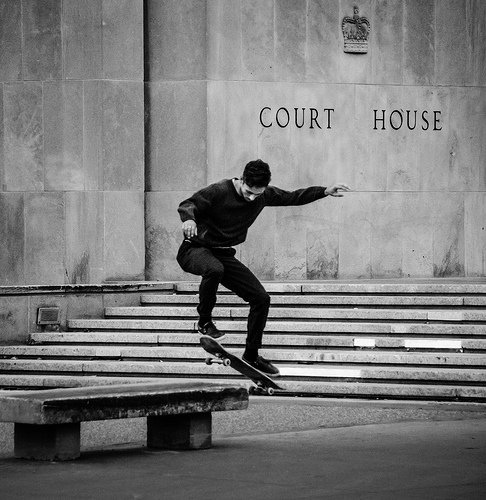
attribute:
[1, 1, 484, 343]
building — concrete, tall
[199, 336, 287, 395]
skateboard — tilited, airborne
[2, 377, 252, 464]
bench — concrete, weathered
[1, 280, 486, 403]
steps — stone, concrete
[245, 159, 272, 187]
hair — thick, dark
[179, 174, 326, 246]
shirt — long-sleeved, dark, sweater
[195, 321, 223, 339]
sneaker — black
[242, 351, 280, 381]
sneaker — black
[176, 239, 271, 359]
pants — dark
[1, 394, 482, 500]
ground — concrete